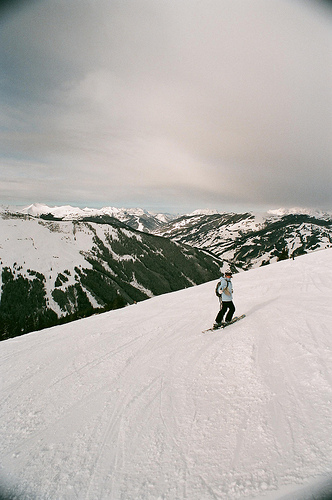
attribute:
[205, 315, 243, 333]
snowboard — green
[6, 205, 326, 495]
snow — part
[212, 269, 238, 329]
person — wearing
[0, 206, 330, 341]
mountains — green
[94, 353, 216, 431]
snow — part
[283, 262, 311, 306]
snow — thick, fluffy, white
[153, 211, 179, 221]
mountaintop — capped, snow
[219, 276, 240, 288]
goggles — dark shade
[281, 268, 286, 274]
snow — part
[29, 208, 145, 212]
mountaintop — snow-capped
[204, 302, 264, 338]
pants — black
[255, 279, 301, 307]
snow — part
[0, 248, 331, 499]
snow — smooth, part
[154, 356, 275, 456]
snow — part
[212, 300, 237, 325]
pants — black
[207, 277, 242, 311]
jacket — light blue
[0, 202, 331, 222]
mountaintop — snow, capped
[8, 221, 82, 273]
snow — part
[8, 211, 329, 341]
ranges — series, mountain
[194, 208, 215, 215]
mountaintop — snow, capped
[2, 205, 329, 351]
snow — sparce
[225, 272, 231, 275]
glasses — black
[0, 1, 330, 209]
sky — overcast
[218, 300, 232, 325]
pants — black